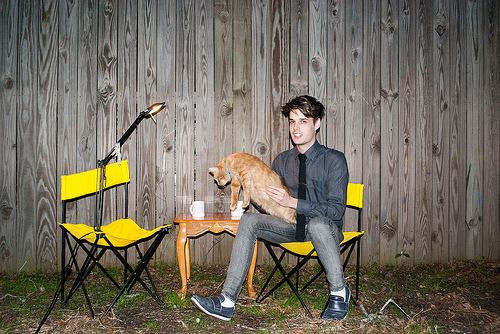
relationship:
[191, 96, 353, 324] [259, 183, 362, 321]
person sitting in chair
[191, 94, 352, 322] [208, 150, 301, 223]
man holding cat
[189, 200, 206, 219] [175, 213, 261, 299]
mug sitting on table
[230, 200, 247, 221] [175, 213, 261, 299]
mug sitting on table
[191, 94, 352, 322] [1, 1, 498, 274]
man sitting by a fence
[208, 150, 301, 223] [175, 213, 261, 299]
cat looking at table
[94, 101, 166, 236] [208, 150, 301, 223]
light facing cat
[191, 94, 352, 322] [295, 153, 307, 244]
man wearing a tie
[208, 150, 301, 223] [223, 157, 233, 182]
cat wearing a collar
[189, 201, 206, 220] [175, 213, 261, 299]
cup sitting on table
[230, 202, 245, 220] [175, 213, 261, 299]
cup sitting on table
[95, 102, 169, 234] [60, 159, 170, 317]
lamp sitting on chair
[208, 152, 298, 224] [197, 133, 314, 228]
cat of cat